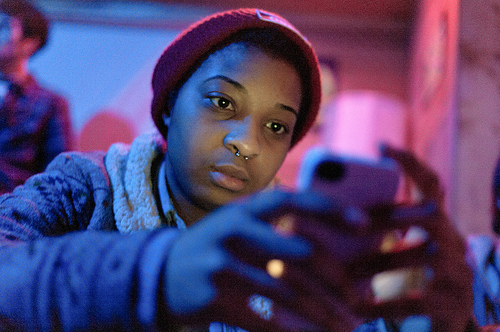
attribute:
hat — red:
[150, 8, 323, 152]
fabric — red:
[167, 40, 202, 68]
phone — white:
[270, 147, 400, 331]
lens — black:
[310, 157, 350, 183]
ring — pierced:
[234, 149, 250, 163]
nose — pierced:
[222, 119, 261, 157]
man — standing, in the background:
[1, 0, 74, 194]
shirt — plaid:
[1, 72, 74, 191]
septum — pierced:
[235, 146, 253, 163]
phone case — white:
[271, 147, 400, 330]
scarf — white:
[104, 128, 164, 231]